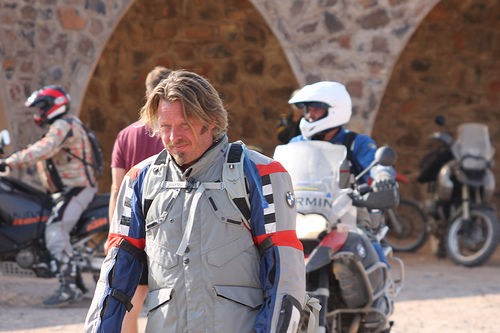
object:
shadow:
[388, 246, 499, 302]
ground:
[0, 250, 499, 331]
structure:
[0, 0, 499, 233]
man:
[0, 84, 102, 307]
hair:
[138, 69, 229, 143]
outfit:
[5, 115, 106, 289]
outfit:
[287, 129, 397, 273]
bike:
[1, 127, 113, 296]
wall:
[370, 0, 498, 238]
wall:
[74, 0, 313, 195]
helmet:
[22, 82, 72, 127]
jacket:
[80, 131, 307, 333]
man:
[86, 68, 309, 332]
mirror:
[373, 144, 398, 166]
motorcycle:
[270, 139, 405, 332]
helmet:
[287, 80, 353, 140]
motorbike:
[415, 114, 497, 267]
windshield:
[272, 139, 352, 224]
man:
[286, 80, 396, 332]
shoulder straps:
[140, 139, 255, 229]